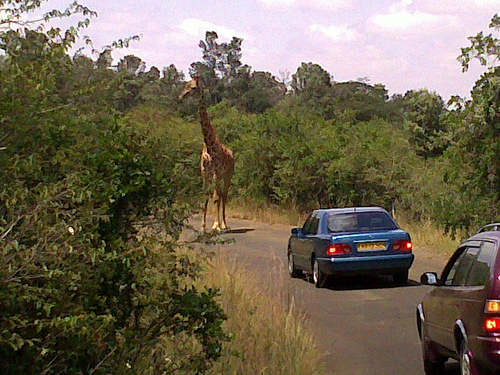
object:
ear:
[195, 78, 199, 86]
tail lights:
[327, 240, 413, 256]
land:
[0, 208, 500, 374]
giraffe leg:
[201, 180, 209, 227]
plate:
[357, 242, 387, 251]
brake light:
[326, 243, 352, 254]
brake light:
[393, 239, 413, 252]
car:
[416, 222, 500, 375]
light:
[392, 240, 413, 252]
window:
[326, 211, 397, 232]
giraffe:
[179, 72, 234, 236]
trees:
[0, 0, 229, 375]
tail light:
[483, 300, 500, 332]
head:
[179, 71, 202, 101]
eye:
[192, 87, 196, 90]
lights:
[326, 242, 352, 255]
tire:
[289, 254, 303, 277]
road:
[137, 201, 500, 375]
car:
[287, 207, 415, 288]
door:
[291, 237, 313, 263]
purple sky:
[0, 0, 500, 104]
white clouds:
[296, 0, 500, 58]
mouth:
[177, 99, 183, 103]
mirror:
[291, 228, 297, 234]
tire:
[313, 257, 329, 288]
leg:
[213, 175, 221, 227]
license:
[357, 242, 386, 251]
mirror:
[421, 271, 440, 287]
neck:
[198, 91, 220, 148]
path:
[131, 200, 500, 375]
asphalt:
[184, 219, 287, 259]